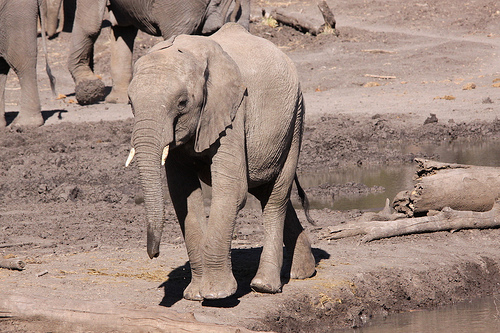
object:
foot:
[199, 273, 239, 301]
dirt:
[312, 49, 500, 101]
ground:
[0, 0, 500, 333]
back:
[209, 21, 283, 52]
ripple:
[459, 309, 490, 327]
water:
[357, 284, 496, 330]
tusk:
[124, 147, 135, 167]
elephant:
[0, 0, 317, 302]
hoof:
[74, 77, 106, 106]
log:
[319, 157, 499, 244]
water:
[134, 142, 499, 213]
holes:
[358, 309, 374, 319]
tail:
[293, 171, 319, 227]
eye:
[176, 95, 188, 110]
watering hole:
[251, 259, 498, 331]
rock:
[256, 0, 339, 34]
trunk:
[131, 112, 174, 259]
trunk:
[124, 116, 175, 257]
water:
[337, 291, 500, 333]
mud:
[75, 80, 106, 106]